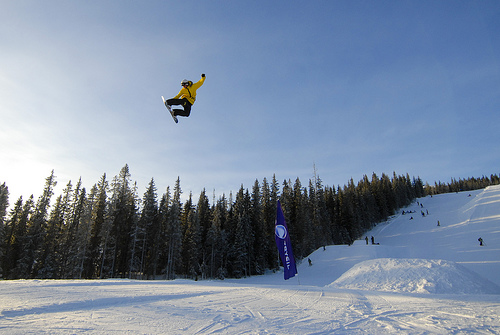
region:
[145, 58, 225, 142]
skier up in the air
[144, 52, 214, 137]
skier up in the air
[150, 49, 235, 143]
skier up in the air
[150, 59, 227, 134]
skier up in the air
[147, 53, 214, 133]
skier up in the air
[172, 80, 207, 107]
the jacket is yellow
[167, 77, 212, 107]
the jacket is yellow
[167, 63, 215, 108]
the jacket is yellow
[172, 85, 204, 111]
the jacket is yellow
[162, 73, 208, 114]
the jacket is yellow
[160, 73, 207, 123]
A snow boarder flies through the air.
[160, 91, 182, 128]
The snow board.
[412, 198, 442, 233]
People on the slope.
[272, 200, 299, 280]
The sponsor's flag.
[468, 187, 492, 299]
The main slope in snow.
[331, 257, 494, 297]
The ramp for tricks.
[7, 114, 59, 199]
The sun glowing in the distance.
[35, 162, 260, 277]
The snow covered trees.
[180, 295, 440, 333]
Tracks in the snow.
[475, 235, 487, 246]
Person on the main slope.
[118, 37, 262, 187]
the person is snowboarding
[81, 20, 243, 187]
the person is making a jump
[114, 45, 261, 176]
the person is high off the floor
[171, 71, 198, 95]
the person is wearing a helmet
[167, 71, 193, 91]
the helmet is white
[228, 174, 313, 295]
the flag is purple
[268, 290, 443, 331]
lines in the snow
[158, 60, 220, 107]
the coat is yellow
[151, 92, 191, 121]
the pants are black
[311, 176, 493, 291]
people are going up the hill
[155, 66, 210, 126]
snowboarder in the air.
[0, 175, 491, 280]
Trees in the background.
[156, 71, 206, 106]
yellow jacket on the man.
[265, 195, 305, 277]
Blue sign on the snow.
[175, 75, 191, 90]
White helmet on the head.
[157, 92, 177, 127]
White color on the snowboard.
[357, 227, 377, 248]
People in the background.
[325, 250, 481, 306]
Pile of snow on the ground.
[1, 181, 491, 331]
snow covering the ground.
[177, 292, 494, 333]
Tracks in the snow.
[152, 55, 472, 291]
a snowboarder is getting some serious air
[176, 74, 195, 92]
a white helmet is on the boy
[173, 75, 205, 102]
a yellow jacket is on the boy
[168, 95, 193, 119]
black pants are on the boy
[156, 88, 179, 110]
a hand may be on the snowboard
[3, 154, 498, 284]
lodgepole pines line the run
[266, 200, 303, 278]
a sign is on the slope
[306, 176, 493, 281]
people are enjoying the slope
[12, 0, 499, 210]
the sky is blue with distant clouds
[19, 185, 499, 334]
shadows are on the well groomed slope